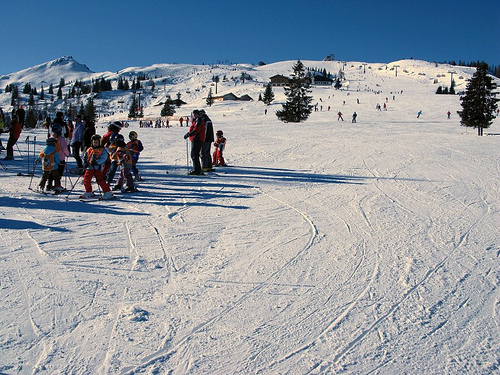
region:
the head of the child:
[88, 134, 104, 148]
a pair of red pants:
[81, 162, 111, 191]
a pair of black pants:
[186, 136, 203, 170]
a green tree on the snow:
[453, 59, 498, 131]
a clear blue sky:
[0, 0, 499, 81]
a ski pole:
[181, 137, 190, 172]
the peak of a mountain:
[51, 49, 80, 66]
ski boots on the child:
[74, 189, 122, 201]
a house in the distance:
[204, 87, 236, 105]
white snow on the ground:
[0, 52, 498, 374]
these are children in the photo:
[36, 121, 148, 201]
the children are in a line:
[84, 128, 147, 186]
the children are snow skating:
[78, 120, 141, 197]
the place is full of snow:
[194, 195, 454, 372]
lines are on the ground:
[182, 218, 467, 373]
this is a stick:
[64, 175, 77, 196]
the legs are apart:
[79, 173, 104, 188]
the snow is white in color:
[290, 241, 445, 338]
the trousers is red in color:
[83, 174, 103, 187]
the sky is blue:
[419, 13, 463, 36]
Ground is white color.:
[276, 185, 419, 267]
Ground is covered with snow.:
[305, 196, 472, 306]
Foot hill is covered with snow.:
[7, 47, 483, 113]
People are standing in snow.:
[3, 88, 263, 199]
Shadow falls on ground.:
[3, 127, 341, 265]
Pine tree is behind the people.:
[50, 50, 491, 135]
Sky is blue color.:
[5, 6, 482, 51]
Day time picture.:
[17, 23, 483, 330]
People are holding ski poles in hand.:
[7, 92, 237, 212]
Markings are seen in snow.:
[46, 196, 483, 341]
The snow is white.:
[170, 254, 314, 358]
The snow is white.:
[164, 205, 388, 350]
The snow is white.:
[62, 170, 299, 340]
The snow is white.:
[125, 137, 392, 285]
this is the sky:
[170, 8, 389, 43]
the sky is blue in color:
[254, 11, 312, 36]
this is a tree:
[288, 57, 308, 119]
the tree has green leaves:
[461, 97, 483, 114]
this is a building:
[216, 91, 243, 98]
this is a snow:
[271, 148, 436, 335]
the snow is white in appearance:
[281, 213, 346, 270]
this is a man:
[185, 108, 205, 164]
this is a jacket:
[197, 126, 206, 134]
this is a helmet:
[91, 133, 102, 137]